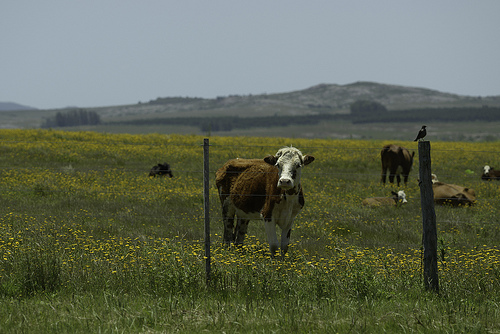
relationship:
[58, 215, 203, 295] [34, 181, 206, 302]
flowers growing in field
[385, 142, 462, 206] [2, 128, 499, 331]
cattle lying down in meadow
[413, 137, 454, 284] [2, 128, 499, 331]
fence post by meadow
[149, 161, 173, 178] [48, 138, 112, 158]
cattle in meadow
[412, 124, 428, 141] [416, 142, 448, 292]
bird on post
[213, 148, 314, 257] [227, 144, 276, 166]
cattle has ear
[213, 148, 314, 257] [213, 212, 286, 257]
cattle has legs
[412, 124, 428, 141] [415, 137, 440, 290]
bird perched on a post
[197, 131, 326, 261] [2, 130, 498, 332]
cattle in field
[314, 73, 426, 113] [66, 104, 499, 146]
hill behind meadow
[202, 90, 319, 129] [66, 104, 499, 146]
hill behind meadow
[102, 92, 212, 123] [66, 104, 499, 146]
hill behind meadow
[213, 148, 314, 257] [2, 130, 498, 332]
cattle standing in a field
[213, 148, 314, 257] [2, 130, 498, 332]
cattle in field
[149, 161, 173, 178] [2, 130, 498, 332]
cattle laying down in field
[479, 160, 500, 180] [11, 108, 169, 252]
cattle laying in field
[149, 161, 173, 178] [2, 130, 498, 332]
cattle laying in field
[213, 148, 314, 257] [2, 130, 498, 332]
cattle laying in field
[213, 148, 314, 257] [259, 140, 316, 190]
cattle has a head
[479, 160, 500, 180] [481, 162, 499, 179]
cattle in field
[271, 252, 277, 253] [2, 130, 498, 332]
flowers are in field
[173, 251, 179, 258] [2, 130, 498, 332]
flowers are in field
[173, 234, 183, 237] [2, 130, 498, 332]
flowers are in field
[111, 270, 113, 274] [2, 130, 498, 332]
flowers are in field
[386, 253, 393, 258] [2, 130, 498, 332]
flowers are in field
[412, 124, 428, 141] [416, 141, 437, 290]
bird on fence post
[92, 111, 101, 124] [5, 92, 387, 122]
tree on hillside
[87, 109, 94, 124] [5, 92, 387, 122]
tree on hillside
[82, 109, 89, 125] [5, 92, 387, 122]
tree on hillside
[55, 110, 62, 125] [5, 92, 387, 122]
tree on hillside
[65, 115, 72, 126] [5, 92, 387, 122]
tree on hillside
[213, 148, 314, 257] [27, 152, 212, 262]
cattle standing in field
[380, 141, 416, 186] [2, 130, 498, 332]
cattle in field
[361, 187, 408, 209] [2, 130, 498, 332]
cattle in field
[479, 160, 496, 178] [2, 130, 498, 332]
cattle in field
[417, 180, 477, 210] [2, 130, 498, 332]
cattle in field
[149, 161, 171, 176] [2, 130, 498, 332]
cattle in field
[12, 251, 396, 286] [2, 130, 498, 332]
wild flowers are in field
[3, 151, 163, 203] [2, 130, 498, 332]
wild flowers are in field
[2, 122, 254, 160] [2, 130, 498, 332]
wild flowers are in field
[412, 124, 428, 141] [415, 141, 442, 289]
bird on a post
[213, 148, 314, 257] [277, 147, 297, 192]
cattle has a face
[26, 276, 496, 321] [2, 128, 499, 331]
grass in meadow